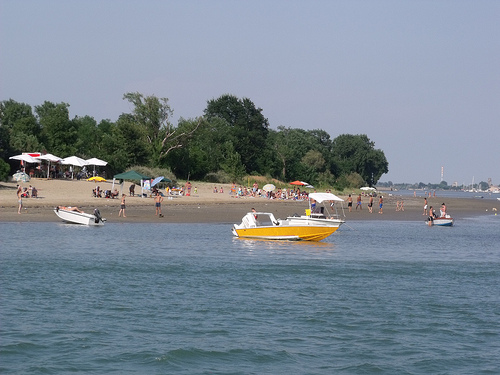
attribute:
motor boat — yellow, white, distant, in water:
[235, 204, 340, 244]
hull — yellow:
[242, 232, 332, 248]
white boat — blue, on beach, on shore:
[52, 191, 109, 237]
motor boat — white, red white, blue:
[419, 213, 453, 227]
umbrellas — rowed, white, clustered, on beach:
[8, 143, 111, 169]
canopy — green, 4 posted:
[106, 175, 147, 191]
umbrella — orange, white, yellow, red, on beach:
[289, 177, 306, 188]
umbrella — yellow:
[83, 168, 117, 185]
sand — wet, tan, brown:
[186, 198, 233, 208]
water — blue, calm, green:
[177, 216, 217, 264]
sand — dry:
[55, 182, 74, 204]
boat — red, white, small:
[422, 204, 457, 230]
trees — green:
[296, 140, 389, 185]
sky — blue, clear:
[337, 32, 401, 61]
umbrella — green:
[151, 174, 165, 190]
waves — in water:
[156, 284, 246, 347]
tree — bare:
[151, 115, 193, 161]